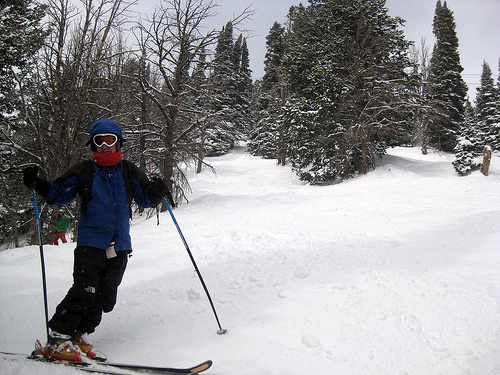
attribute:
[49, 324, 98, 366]
boots — gold, red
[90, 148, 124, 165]
scarf — orange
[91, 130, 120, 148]
goggles — white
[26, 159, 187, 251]
jacket — black, blue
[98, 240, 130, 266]
tag — white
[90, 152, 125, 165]
scarf — red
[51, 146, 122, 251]
scarf — red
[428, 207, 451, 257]
snow — white